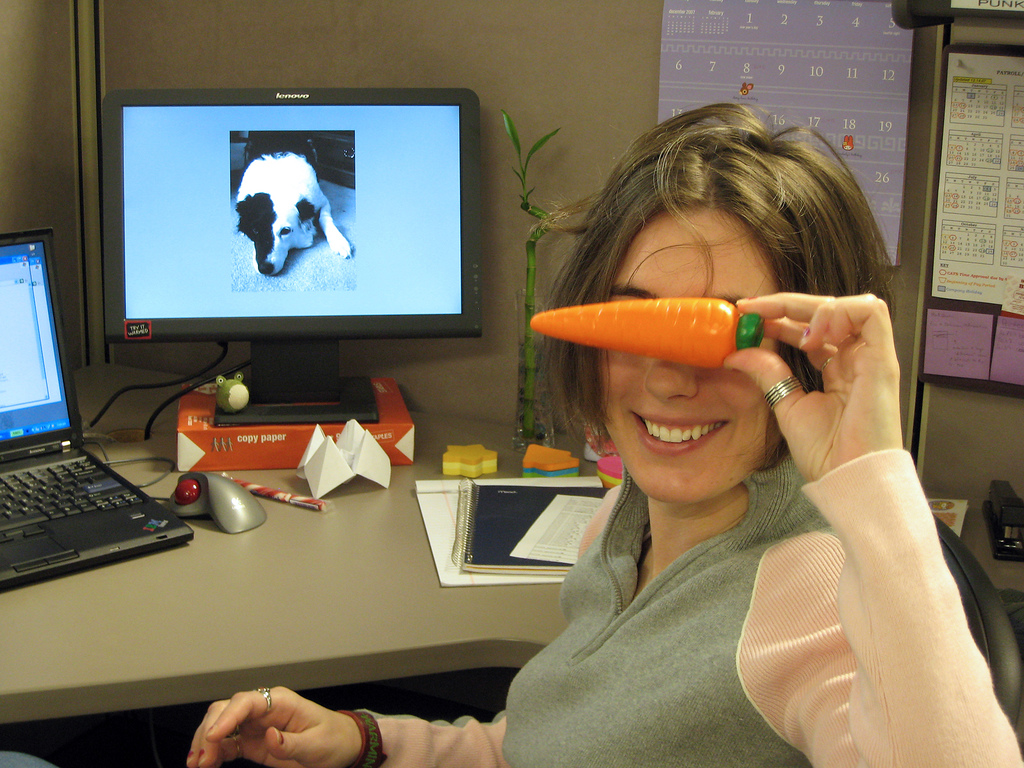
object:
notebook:
[453, 477, 611, 580]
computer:
[0, 227, 192, 589]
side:
[0, 0, 109, 371]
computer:
[102, 87, 484, 428]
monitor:
[102, 88, 485, 342]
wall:
[891, 0, 1024, 594]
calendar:
[930, 52, 1023, 306]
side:
[891, 1, 1023, 649]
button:
[175, 478, 201, 505]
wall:
[98, 0, 914, 449]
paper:
[297, 419, 392, 499]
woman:
[185, 103, 1024, 768]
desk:
[0, 410, 1021, 724]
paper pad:
[522, 444, 579, 477]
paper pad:
[597, 456, 622, 489]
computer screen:
[0, 241, 71, 442]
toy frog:
[216, 373, 249, 412]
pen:
[233, 479, 326, 511]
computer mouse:
[170, 471, 268, 534]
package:
[177, 378, 415, 472]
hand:
[724, 292, 901, 481]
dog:
[236, 151, 353, 275]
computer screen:
[123, 106, 462, 319]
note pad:
[442, 444, 497, 478]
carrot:
[530, 298, 765, 368]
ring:
[764, 375, 804, 409]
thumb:
[724, 348, 807, 420]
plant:
[500, 108, 561, 453]